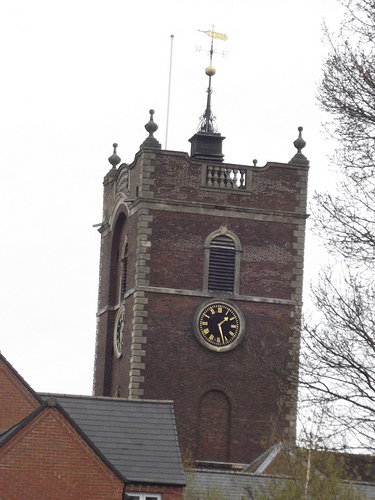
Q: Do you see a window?
A: Yes, there is a window.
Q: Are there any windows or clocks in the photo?
A: Yes, there is a window.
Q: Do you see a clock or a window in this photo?
A: Yes, there is a window.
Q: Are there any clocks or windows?
A: Yes, there is a window.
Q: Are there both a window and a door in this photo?
A: No, there is a window but no doors.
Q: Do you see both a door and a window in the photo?
A: No, there is a window but no doors.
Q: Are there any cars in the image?
A: No, there are no cars.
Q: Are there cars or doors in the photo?
A: No, there are no cars or doors.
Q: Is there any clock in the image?
A: Yes, there is a clock.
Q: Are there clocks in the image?
A: Yes, there is a clock.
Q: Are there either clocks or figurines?
A: Yes, there is a clock.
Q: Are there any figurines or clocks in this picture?
A: Yes, there is a clock.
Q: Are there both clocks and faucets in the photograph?
A: No, there is a clock but no faucets.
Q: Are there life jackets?
A: No, there are no life jackets.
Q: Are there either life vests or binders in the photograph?
A: No, there are no life vests or binders.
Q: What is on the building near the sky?
A: The clock is on the clock tower.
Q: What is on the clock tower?
A: The clock is on the clock tower.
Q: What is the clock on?
A: The clock is on the clock tower.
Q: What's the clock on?
A: The clock is on the clock tower.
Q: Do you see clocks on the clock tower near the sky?
A: Yes, there is a clock on the clock tower.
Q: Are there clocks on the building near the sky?
A: Yes, there is a clock on the clock tower.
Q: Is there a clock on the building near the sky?
A: Yes, there is a clock on the clock tower.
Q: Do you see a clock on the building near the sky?
A: Yes, there is a clock on the clock tower.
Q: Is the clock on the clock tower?
A: Yes, the clock is on the clock tower.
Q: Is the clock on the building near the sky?
A: Yes, the clock is on the clock tower.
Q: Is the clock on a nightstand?
A: No, the clock is on the clock tower.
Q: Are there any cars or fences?
A: No, there are no cars or fences.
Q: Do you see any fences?
A: No, there are no fences.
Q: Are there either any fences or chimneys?
A: No, there are no fences or chimneys.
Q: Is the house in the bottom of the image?
A: Yes, the house is in the bottom of the image.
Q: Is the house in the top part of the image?
A: No, the house is in the bottom of the image.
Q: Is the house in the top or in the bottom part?
A: The house is in the bottom of the image.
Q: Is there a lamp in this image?
A: No, there are no lamps.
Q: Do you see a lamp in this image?
A: No, there are no lamps.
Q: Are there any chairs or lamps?
A: No, there are no lamps or chairs.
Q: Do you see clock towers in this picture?
A: Yes, there is a clock tower.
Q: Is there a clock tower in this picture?
A: Yes, there is a clock tower.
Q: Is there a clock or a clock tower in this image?
A: Yes, there is a clock tower.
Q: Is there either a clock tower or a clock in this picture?
A: Yes, there is a clock tower.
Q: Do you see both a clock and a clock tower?
A: Yes, there are both a clock tower and a clock.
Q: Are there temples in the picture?
A: No, there are no temples.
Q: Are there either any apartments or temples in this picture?
A: No, there are no temples or apartments.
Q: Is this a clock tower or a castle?
A: This is a clock tower.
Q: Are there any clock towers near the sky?
A: Yes, there is a clock tower near the sky.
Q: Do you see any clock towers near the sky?
A: Yes, there is a clock tower near the sky.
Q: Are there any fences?
A: No, there are no fences.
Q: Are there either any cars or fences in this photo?
A: No, there are no fences or cars.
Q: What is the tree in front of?
A: The tree is in front of the window.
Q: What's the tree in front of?
A: The tree is in front of the window.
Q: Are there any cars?
A: No, there are no cars.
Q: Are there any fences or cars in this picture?
A: No, there are no cars or fences.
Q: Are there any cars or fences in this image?
A: No, there are no cars or fences.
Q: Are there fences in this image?
A: No, there are no fences.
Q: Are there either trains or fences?
A: No, there are no fences or trains.